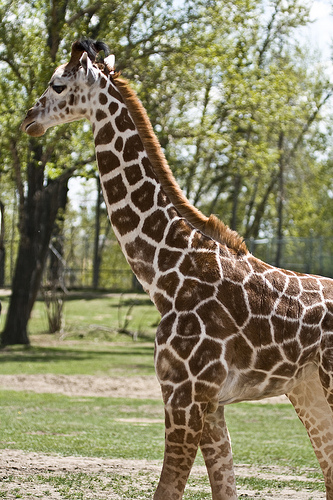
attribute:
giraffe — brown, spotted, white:
[20, 36, 332, 499]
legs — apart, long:
[155, 403, 240, 499]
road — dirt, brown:
[0, 447, 328, 498]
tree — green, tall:
[0, 1, 323, 345]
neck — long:
[86, 110, 254, 314]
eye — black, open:
[51, 83, 69, 95]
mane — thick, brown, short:
[111, 69, 251, 255]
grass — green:
[3, 388, 326, 472]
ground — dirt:
[0, 371, 294, 405]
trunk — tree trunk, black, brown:
[3, 174, 70, 345]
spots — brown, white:
[53, 71, 332, 498]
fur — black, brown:
[88, 81, 331, 499]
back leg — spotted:
[288, 380, 333, 499]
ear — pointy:
[79, 50, 99, 86]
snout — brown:
[24, 106, 38, 119]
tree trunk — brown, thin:
[242, 92, 333, 242]